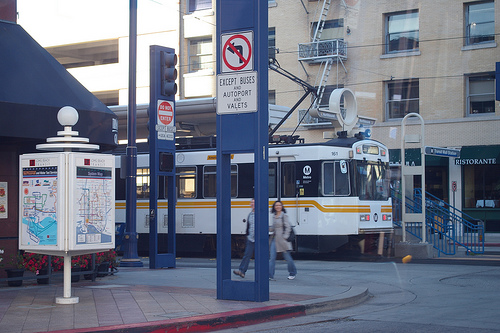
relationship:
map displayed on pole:
[70, 153, 115, 249] [54, 251, 79, 304]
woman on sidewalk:
[269, 201, 297, 282] [1, 265, 369, 333]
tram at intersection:
[108, 137, 393, 260] [365, 261, 498, 333]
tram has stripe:
[108, 137, 393, 260] [116, 198, 393, 213]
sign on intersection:
[156, 99, 175, 127] [283, 234, 499, 333]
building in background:
[17, 1, 499, 248] [17, 2, 499, 253]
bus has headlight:
[108, 137, 393, 260] [359, 214, 371, 222]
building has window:
[17, 1, 499, 248] [381, 77, 422, 122]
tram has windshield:
[108, 137, 393, 260] [354, 159, 391, 201]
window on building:
[462, 0, 499, 51] [17, 1, 499, 248]